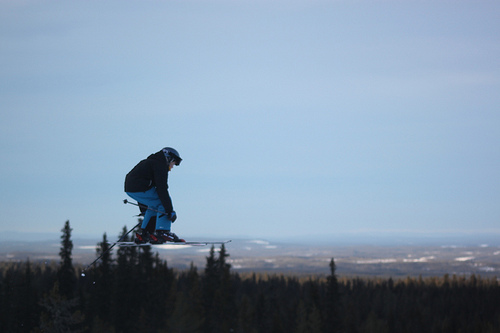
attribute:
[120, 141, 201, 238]
person — man, skating, flying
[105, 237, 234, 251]
skis — pair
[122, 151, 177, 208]
coat — black, jacket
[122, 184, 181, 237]
pants — blue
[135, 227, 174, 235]
shoes — black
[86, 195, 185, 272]
ski poles — black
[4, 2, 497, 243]
sky — blue, clear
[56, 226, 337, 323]
trees — green, growing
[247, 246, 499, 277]
ground — brown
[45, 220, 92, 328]
tree — big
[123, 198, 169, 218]
ski pole — gray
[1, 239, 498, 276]
hills — distant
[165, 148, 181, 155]
helmet — gray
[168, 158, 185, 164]
goggles — black